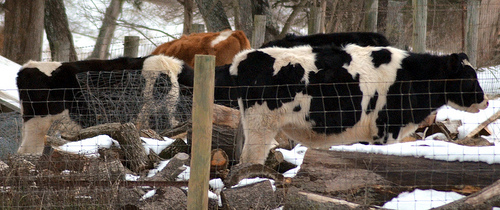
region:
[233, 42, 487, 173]
a black and white standing cow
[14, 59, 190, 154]
a black and white standing cow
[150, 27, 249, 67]
a brown and white standing cow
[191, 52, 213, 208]
a wood fence pole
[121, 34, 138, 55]
a wood fence pole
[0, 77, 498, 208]
a long stretch of net fencing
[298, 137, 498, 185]
a snow covered log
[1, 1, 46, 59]
a brown grey tree trunk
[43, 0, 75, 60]
a brown grey tree trunk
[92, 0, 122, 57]
a brown grey tree trunk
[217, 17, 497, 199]
this is a cow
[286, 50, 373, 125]
black spots on the cow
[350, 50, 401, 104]
white spots on the cow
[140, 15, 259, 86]
brown cow in background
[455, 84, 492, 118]
white mouth on cow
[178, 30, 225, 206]
a wooden fence post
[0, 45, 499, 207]
a wire mesh fence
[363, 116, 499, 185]
snow on the ground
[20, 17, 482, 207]
group of cows in a closure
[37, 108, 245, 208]
cut logs on the ground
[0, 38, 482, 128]
group of cows together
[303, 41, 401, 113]
black and white side of cow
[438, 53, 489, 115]
black and white head of cow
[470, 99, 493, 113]
white face of cow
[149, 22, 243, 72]
brown and white body of cow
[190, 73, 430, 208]
metal wire fence of structure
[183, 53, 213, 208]
brown fence post on ground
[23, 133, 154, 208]
cut up long son ground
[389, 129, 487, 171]
white snow on the ground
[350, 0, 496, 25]
bottom parts of trees in back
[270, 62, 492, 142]
black and white cow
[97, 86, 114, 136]
chicken wire on fence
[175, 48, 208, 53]
brown and white cow in back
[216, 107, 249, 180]
pieces of log behind cow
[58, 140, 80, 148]
snow on a stump of tree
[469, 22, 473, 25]
wooden wall of building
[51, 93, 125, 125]
smaller black and white cow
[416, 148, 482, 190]
snow on larger wooden log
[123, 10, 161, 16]
bare branch trees in back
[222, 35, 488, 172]
black and white cow in field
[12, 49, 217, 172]
black and white cow standing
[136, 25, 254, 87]
brown and white cow standing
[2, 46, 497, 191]
metal wire fence supported by wooden poles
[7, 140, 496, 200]
rocky terrain under cows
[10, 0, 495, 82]
trees in background lining ground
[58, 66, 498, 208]
snow covering rocky ground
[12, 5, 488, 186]
three cows standing in enclosed field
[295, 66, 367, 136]
large black patch on white cow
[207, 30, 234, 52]
small white patch on brown cow